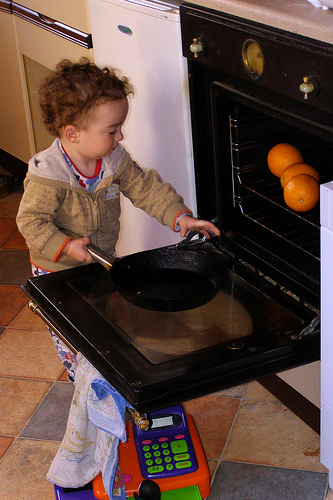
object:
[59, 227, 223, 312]
skillet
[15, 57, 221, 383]
child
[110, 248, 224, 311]
black pan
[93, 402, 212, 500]
toy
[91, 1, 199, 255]
fridge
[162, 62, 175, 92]
part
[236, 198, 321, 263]
rack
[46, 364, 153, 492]
water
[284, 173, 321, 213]
orange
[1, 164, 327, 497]
floor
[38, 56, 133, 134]
red hair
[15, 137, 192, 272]
brown jacket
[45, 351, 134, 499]
blanket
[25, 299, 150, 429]
handle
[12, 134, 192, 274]
jacket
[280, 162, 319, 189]
orange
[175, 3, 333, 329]
oven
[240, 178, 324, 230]
rack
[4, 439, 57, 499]
tiles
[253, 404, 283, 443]
part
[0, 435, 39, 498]
ground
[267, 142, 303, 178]
orange